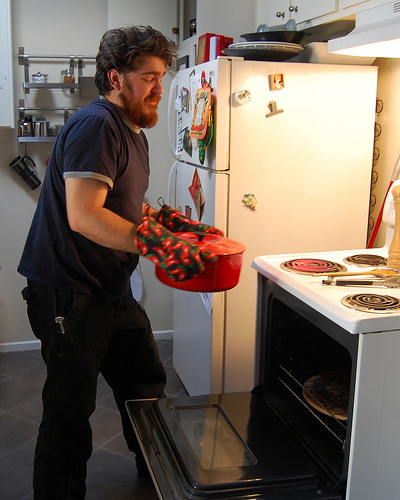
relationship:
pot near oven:
[140, 209, 253, 296] [132, 230, 399, 491]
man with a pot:
[17, 24, 167, 500] [140, 209, 253, 296]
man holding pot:
[17, 24, 167, 500] [140, 209, 253, 296]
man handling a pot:
[17, 24, 167, 500] [140, 209, 253, 296]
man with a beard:
[17, 24, 225, 499] [127, 96, 158, 127]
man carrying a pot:
[17, 24, 225, 499] [140, 209, 253, 296]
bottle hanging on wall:
[8, 155, 42, 189] [0, 0, 182, 348]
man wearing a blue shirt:
[17, 24, 225, 499] [16, 99, 152, 297]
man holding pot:
[17, 24, 225, 499] [140, 209, 253, 296]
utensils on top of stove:
[322, 267, 398, 288] [123, 181, 398, 498]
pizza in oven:
[305, 371, 349, 420] [132, 230, 399, 491]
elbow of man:
[66, 212, 86, 235] [17, 24, 167, 500]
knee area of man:
[137, 359, 167, 398] [17, 24, 167, 500]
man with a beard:
[17, 24, 167, 500] [127, 96, 158, 127]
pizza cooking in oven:
[305, 371, 349, 420] [132, 230, 399, 491]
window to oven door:
[176, 403, 258, 470] [125, 394, 348, 500]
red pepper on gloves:
[182, 245, 188, 267] [134, 204, 223, 284]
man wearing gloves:
[17, 24, 225, 499] [134, 204, 223, 284]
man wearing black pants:
[17, 24, 225, 499] [19, 277, 201, 500]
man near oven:
[17, 24, 167, 500] [132, 230, 399, 491]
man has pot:
[17, 24, 167, 500] [140, 209, 253, 296]